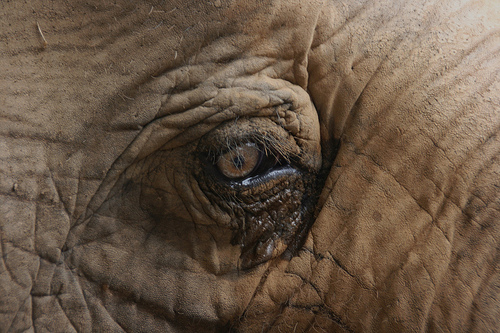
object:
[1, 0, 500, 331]
face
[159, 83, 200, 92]
wrinkle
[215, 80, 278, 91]
wrinkle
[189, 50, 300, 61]
wrinkle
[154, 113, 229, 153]
wrinkle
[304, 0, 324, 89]
wrinkle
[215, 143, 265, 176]
eyeball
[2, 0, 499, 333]
animal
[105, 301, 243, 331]
wrinkle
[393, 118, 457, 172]
wrinkle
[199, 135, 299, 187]
eye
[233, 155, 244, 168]
pupil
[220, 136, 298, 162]
eye lashes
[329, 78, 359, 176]
wrinkle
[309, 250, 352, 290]
wrinkle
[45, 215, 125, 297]
wrinkle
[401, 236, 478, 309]
wrinkle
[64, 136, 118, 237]
wrinkle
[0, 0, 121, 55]
wrinkle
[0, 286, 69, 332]
wrinkle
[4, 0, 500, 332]
skin